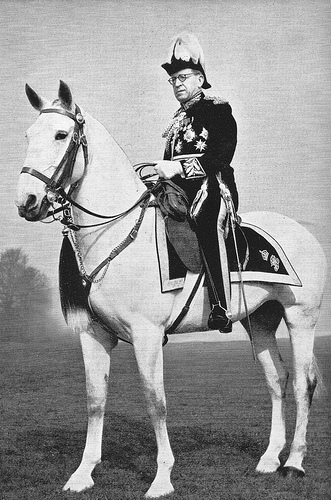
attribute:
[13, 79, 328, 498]
horse — white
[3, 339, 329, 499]
grass — short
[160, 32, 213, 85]
cap — white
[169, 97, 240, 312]
uniform — black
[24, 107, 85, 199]
bridal — leather